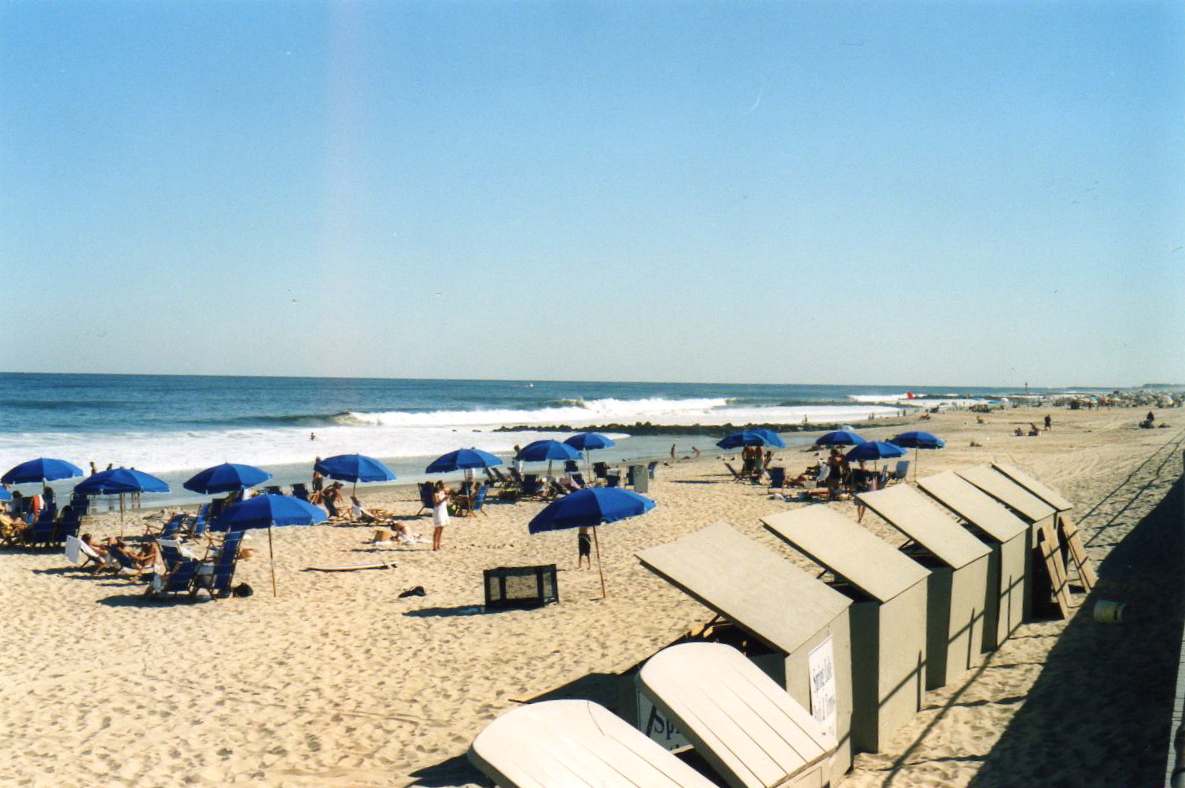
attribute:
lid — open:
[637, 514, 858, 654]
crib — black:
[482, 557, 566, 606]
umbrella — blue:
[527, 475, 649, 589]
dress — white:
[426, 496, 449, 526]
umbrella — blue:
[529, 477, 658, 595]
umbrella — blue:
[215, 488, 339, 595]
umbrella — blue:
[79, 464, 169, 528]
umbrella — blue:
[8, 458, 76, 496]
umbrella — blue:
[430, 443, 507, 488]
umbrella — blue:
[893, 421, 942, 479]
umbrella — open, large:
[72, 460, 166, 535]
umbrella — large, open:
[6, 443, 81, 537]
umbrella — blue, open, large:
[314, 445, 400, 520]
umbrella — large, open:
[424, 439, 516, 516]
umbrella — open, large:
[510, 433, 587, 504]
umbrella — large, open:
[831, 437, 906, 499]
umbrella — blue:
[523, 482, 663, 606]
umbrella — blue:
[193, 489, 339, 607]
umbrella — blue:
[411, 439, 518, 525]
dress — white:
[424, 502, 460, 540]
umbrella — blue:
[499, 433, 593, 517]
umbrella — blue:
[559, 417, 619, 496]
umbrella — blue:
[1, 452, 91, 533]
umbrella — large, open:
[206, 489, 335, 594]